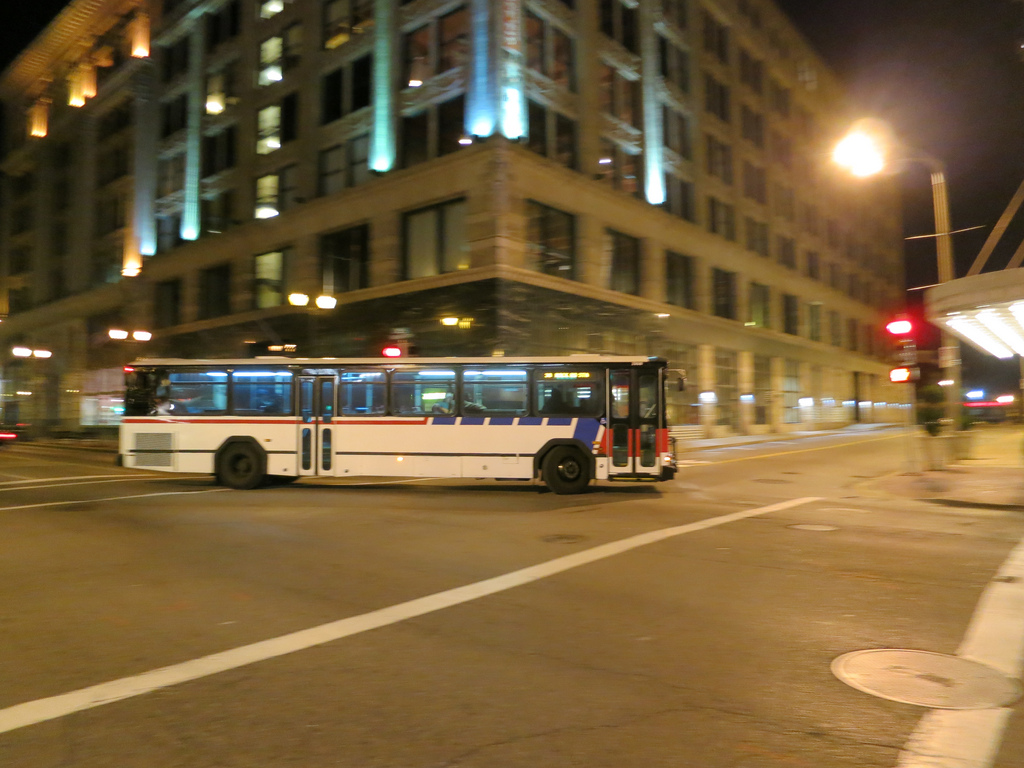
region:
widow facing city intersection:
[396, 200, 442, 281]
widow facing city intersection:
[437, 191, 475, 272]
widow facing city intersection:
[341, 124, 376, 191]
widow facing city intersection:
[192, 262, 232, 326]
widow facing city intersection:
[522, 197, 583, 281]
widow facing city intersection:
[601, 218, 650, 299]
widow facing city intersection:
[660, 238, 698, 308]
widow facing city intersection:
[742, 279, 774, 331]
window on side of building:
[151, 89, 191, 135]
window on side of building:
[156, 224, 185, 256]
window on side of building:
[83, 186, 123, 238]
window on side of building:
[86, 92, 135, 150]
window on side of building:
[513, 4, 551, 77]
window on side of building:
[598, 57, 618, 115]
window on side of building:
[625, 69, 645, 127]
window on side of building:
[660, 165, 680, 217]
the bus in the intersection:
[113, 348, 680, 495]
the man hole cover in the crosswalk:
[793, 519, 844, 532]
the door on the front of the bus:
[609, 367, 664, 476]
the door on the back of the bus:
[296, 373, 336, 475]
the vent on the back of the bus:
[129, 430, 177, 468]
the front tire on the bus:
[541, 445, 593, 491]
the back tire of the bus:
[215, 440, 269, 488]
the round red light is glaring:
[888, 317, 911, 338]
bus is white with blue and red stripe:
[114, 356, 675, 493]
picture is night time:
[1, 8, 1008, 767]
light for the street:
[125, 119, 969, 767]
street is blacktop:
[10, 418, 1022, 761]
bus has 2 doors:
[121, 358, 673, 489]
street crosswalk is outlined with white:
[7, 507, 1022, 763]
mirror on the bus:
[658, 355, 690, 400]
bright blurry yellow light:
[822, 120, 890, 184]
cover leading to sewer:
[830, 633, 1021, 713]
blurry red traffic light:
[872, 316, 926, 345]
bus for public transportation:
[117, 332, 683, 487]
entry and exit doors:
[610, 364, 667, 470]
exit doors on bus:
[293, 366, 332, 474]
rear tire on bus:
[215, 433, 266, 492]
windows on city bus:
[344, 372, 532, 412]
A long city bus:
[99, 327, 691, 504]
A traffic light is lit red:
[867, 296, 928, 380]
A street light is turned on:
[806, 98, 984, 475]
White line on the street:
[0, 481, 832, 758]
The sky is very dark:
[757, 0, 1014, 302]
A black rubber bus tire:
[529, 431, 607, 505]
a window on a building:
[315, 62, 342, 121]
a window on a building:
[343, 55, 373, 109]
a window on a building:
[405, 26, 428, 88]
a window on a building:
[438, 17, 468, 71]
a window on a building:
[277, 159, 296, 207]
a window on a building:
[283, 86, 303, 144]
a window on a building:
[324, 152, 343, 191]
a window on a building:
[350, 127, 373, 179]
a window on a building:
[398, 103, 428, 162]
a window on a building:
[436, 98, 460, 155]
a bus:
[110, 350, 662, 496]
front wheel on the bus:
[543, 439, 598, 488]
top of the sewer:
[841, 628, 998, 711]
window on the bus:
[462, 367, 526, 413]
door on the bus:
[609, 374, 654, 472]